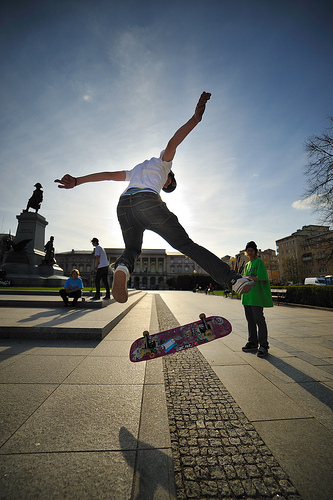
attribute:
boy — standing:
[237, 236, 281, 363]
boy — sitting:
[58, 269, 89, 315]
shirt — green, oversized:
[234, 256, 285, 314]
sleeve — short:
[254, 260, 276, 283]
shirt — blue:
[60, 277, 88, 293]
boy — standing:
[85, 230, 116, 305]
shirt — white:
[91, 244, 116, 273]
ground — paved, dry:
[2, 332, 333, 500]